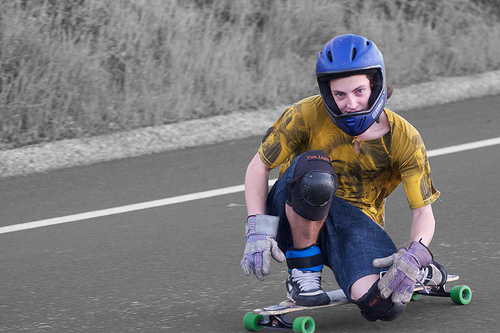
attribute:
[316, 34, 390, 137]
helmet — purple, blue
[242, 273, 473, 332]
skateboard — green, white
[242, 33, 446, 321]
boy — skateboarding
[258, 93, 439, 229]
shirt — gold, black, yellow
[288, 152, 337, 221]
knee pad — black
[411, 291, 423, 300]
wheel — green, black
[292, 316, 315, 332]
wheel — green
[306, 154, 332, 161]
print — red